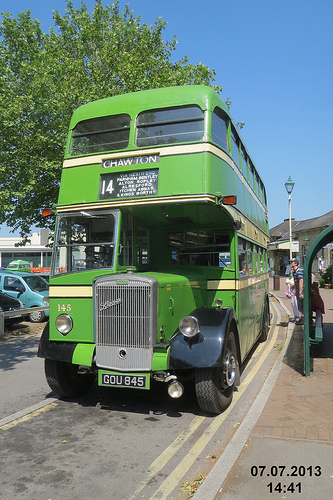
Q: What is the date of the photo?
A: 07/07/2013.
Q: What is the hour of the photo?
A: 14:41.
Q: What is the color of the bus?
A: Is green.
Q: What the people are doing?
A: Waiting to get on the bus.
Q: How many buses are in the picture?
A: One.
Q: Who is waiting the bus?
A: The people.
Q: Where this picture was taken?
A: In a bus stop.